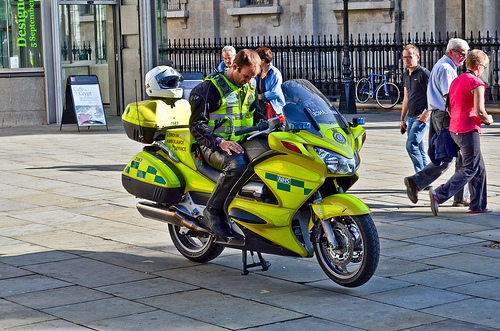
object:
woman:
[429, 48, 495, 217]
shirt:
[447, 72, 486, 135]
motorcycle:
[121, 78, 381, 288]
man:
[188, 48, 262, 235]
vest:
[204, 72, 256, 143]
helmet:
[144, 65, 185, 99]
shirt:
[402, 65, 430, 118]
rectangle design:
[146, 165, 158, 175]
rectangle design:
[137, 169, 146, 178]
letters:
[16, 37, 28, 48]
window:
[0, 0, 43, 71]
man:
[401, 43, 433, 190]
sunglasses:
[452, 49, 469, 57]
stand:
[242, 248, 268, 275]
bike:
[355, 66, 400, 109]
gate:
[160, 30, 500, 103]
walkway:
[1, 125, 500, 329]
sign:
[60, 75, 109, 134]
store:
[1, 0, 147, 128]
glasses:
[402, 55, 418, 58]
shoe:
[428, 187, 440, 216]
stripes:
[432, 193, 440, 203]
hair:
[446, 38, 471, 55]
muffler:
[136, 201, 212, 233]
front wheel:
[310, 214, 380, 288]